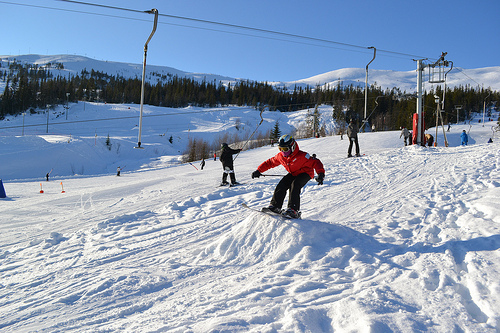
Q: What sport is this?
A: Snowboarding.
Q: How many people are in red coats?
A: One.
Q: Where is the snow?
A: On the ground.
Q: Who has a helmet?
A: The snowboarders.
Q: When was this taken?
A: Daytime.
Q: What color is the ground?
A: White.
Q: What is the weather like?
A: Sunny and cold.